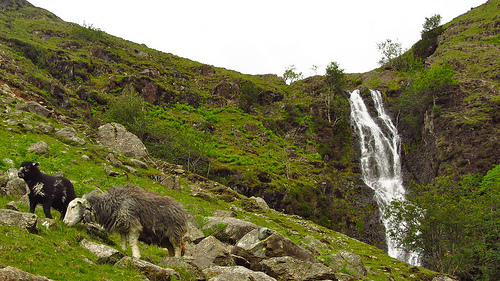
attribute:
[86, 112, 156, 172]
boulder — large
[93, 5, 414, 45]
sky — white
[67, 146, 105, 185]
grass — green